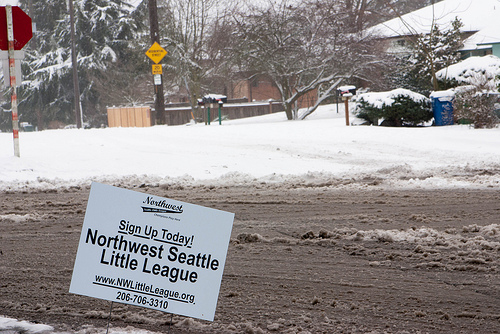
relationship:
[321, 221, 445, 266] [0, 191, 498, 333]
slush on road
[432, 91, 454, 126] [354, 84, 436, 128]
bin in bushes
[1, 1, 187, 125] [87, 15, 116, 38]
tree has leaves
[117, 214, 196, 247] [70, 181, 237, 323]
writing on sign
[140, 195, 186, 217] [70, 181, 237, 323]
logo on sign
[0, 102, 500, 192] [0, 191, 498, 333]
snow in road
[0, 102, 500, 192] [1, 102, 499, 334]
snow on ground